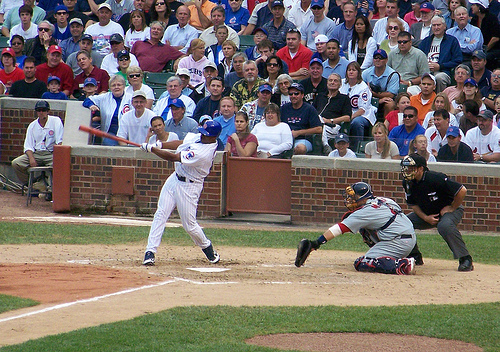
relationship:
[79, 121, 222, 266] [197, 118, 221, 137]
baseball player wearing helmet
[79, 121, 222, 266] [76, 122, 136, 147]
baseball player with bat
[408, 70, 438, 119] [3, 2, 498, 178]
person in crowd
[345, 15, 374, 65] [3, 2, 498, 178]
person in crowd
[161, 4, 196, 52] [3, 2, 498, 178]
person in crowd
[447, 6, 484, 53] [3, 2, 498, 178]
person in crowd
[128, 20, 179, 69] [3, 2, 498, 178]
person in crowd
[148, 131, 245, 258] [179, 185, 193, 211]
uniform with stripes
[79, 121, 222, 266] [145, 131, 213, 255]
baseball player wearing uniform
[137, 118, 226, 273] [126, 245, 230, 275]
baseball player wearing shoes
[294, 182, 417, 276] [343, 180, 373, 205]
catcher wearing safety helmet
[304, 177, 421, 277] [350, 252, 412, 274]
catcher wearing guard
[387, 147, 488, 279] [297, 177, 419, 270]
umpire crouches behind catcher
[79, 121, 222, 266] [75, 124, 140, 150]
baseball player swinging bat